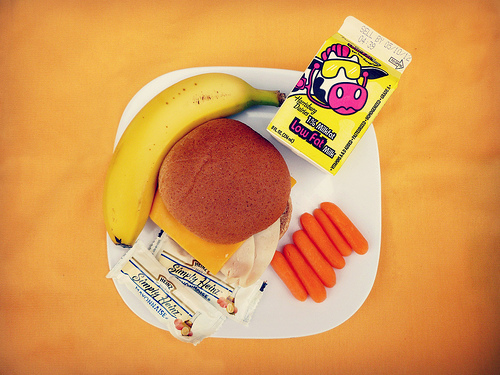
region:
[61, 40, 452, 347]
A kid's plate at lunch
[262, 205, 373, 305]
Several orange carrots on the plate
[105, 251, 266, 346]
A packet of mayo on the plate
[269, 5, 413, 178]
A box of low fat milk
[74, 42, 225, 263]
A yellow banana on the plate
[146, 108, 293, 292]
A turkey sandwich on the plate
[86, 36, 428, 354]
The plate on the table is white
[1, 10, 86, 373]
The table is light brown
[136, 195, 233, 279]
The cheese on the sandwich is yellow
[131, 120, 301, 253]
The bread on the sandwich is wheat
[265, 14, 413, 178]
A carton of low fat milk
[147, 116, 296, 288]
A meat and cheese sandwitch on a bun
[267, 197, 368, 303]
Six orange carrots in a row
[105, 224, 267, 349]
Two packets of mayonnaise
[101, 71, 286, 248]
A yellow banana with peel on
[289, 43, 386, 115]
A pink, white, and black cow wearing yellow sunglasses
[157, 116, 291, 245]
The top of a wheat bun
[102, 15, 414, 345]
A plate of healthy food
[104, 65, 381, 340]
A white plate with food on it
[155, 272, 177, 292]
The Heinz logo on a mayonnaise package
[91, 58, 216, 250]
fresh yellow banana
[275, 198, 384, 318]
fresh orange carrots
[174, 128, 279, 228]
brown hamburger bun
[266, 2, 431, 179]
small carton of milk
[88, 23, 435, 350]
food on a white plate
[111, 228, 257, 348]
two packets of mayonnaise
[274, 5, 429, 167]
low fat milk in carton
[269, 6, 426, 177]
yellow and purple carton of milk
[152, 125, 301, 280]
hamburger with cheese and meat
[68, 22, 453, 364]
plate on brown table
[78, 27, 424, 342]
a plate with food on it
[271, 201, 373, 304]
carrots lined up on a plate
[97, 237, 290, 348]
two packets of mayonaise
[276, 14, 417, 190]
one carton of low fat milk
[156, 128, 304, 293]
a sandwich with meat and cheese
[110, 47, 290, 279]
one unpeeled banana on plate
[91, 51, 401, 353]
a square white plate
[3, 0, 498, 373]
an orange table cloth under plate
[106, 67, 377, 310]
a sandwich with fruit and vegetables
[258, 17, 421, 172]
a yellow milk carton with cow on it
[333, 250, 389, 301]
part of a plate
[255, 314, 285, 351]
edge of a dih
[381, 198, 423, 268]
part of a floor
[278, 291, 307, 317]
part of a plate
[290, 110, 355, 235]
prt of a box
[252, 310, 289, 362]
edge of a plate